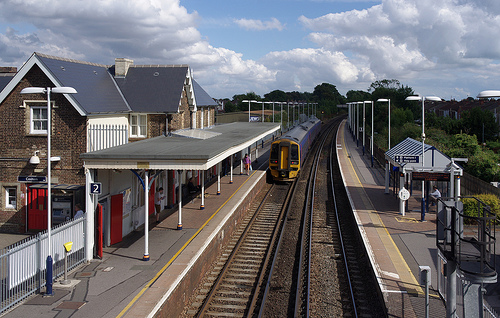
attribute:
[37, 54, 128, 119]
roof — gray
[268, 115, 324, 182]
train — at the station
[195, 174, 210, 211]
pole — metal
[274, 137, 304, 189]
train front — yellow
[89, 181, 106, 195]
2 — white number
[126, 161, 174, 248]
pole — white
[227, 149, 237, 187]
pole — white